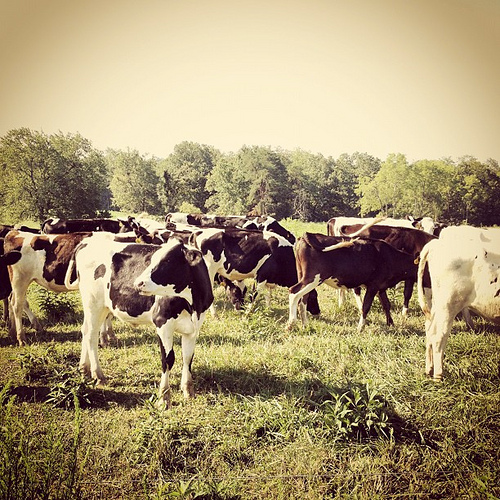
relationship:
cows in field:
[0, 224, 499, 406] [2, 268, 499, 499]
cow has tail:
[69, 228, 216, 421] [56, 246, 95, 312]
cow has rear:
[69, 228, 216, 421] [55, 235, 129, 304]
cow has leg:
[69, 228, 216, 421] [136, 326, 217, 402]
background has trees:
[6, 6, 492, 250] [10, 118, 499, 223]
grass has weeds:
[127, 362, 491, 498] [331, 384, 404, 449]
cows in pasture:
[0, 224, 499, 406] [2, 268, 499, 499]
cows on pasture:
[0, 224, 499, 406] [2, 268, 499, 499]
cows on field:
[0, 224, 499, 406] [2, 268, 499, 499]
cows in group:
[0, 224, 499, 406] [320, 202, 498, 359]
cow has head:
[69, 228, 216, 421] [120, 242, 210, 307]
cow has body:
[69, 228, 216, 421] [99, 247, 182, 352]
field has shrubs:
[2, 268, 499, 499] [409, 162, 499, 217]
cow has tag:
[69, 228, 216, 421] [179, 249, 197, 260]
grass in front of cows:
[127, 362, 491, 498] [0, 224, 499, 406]